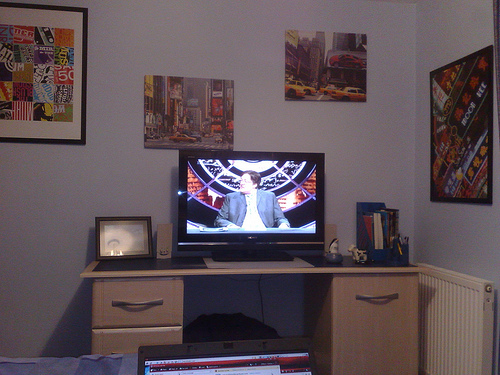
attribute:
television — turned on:
[179, 149, 324, 249]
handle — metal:
[109, 295, 165, 309]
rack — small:
[354, 200, 413, 268]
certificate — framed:
[92, 211, 156, 258]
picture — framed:
[1, 13, 87, 146]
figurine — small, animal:
[340, 241, 378, 272]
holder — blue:
[360, 205, 388, 267]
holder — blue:
[393, 237, 413, 263]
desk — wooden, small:
[77, 246, 421, 372]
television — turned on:
[172, 138, 334, 255]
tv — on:
[172, 147, 334, 253]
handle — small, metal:
[107, 296, 165, 308]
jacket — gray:
[212, 189, 294, 226]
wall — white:
[0, 4, 500, 351]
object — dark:
[182, 303, 282, 342]